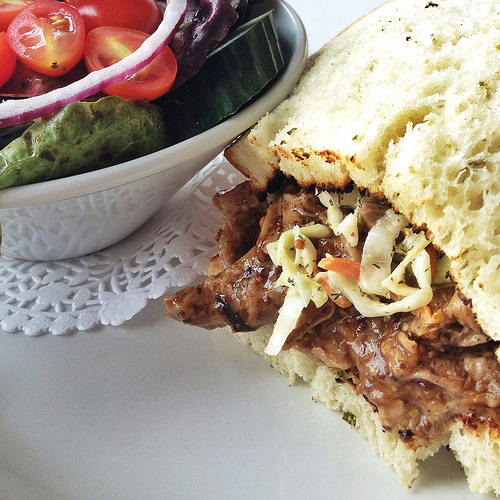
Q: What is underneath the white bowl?
A: White doily.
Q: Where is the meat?
A: In the sandwich.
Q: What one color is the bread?
A: White.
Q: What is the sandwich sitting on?
A: White table.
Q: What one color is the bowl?
A: White.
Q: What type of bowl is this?
A: Ceramic.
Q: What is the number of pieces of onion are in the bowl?
A: One.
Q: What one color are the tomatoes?
A: Red.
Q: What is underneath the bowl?
A: A doily.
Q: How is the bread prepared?
A: Toasted.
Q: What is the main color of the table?
A: White.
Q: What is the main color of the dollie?
A: White.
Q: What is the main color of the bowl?
A: White.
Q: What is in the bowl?
A: Salad.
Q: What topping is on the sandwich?
A: Coleslaw.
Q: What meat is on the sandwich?
A: Steak.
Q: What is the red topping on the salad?
A: Tomatoes.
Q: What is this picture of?
A: Food.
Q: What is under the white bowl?
A: Doily.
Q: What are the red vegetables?
A: Tomatoes.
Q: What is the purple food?
A: Onions.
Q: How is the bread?
A: Toasted.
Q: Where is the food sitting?
A: On a table.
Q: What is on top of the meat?
A: Coleslaw.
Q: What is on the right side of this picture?
A: A sandwich.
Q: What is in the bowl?
A: A salad.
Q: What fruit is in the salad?
A: A tomato.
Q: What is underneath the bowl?
A: A doily.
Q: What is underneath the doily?
A: A table.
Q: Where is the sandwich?
A: On the table.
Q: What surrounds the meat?
A: Bread.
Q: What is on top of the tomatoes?
A: An onion.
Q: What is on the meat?
A: Cole slaw.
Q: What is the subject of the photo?
A: Food.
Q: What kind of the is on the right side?
A: Sandwich.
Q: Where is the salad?
A: Bowl.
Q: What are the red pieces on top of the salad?
A: Tomatoes.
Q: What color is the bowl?
A: White.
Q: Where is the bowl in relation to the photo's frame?
A: Upper left corner.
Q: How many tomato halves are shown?
A: Five.